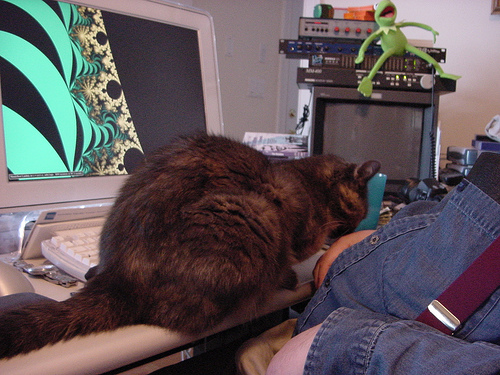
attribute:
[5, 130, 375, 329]
cat — black, sleeping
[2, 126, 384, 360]
cat — black, sleeping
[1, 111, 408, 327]
cat — calico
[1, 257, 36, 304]
computer mouse — gray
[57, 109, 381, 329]
cat — black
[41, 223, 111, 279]
keyboard — white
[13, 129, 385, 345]
cat — sleeping, black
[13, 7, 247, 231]
moniter — white, flat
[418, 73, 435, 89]
silver knob — large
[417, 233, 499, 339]
suspender — brown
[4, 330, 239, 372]
desk — white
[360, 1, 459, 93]
kermit — green, black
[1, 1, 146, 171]
image — white, black, green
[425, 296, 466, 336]
buckle — silver, metal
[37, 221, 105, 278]
keyboard — white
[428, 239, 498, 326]
strap — maroon, nylon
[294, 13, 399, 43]
electronics — gray, red, black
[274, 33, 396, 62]
electronics — black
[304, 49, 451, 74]
electronics — black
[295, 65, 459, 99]
electronics — black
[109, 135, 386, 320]
cat — black, sleeping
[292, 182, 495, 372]
shirt — denim, blue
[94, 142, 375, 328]
cat — calico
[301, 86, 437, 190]
television — small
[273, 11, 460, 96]
components — cable, video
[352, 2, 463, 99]
doll — Kermit the Frog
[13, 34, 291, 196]
monitor — computer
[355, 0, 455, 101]
frog — green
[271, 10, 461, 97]
electronics — black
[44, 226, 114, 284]
keyboard — white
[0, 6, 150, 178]
design — black, green, white, 3D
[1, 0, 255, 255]
monitor — computer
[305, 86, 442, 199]
tv — black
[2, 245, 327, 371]
desk — white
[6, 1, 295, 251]
screen — black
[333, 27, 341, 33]
knob — red, round, black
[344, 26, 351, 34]
knob — round, red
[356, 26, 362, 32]
knob — red, round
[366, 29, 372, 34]
knob — round, red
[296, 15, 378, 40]
machine — silver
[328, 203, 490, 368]
shirt — denim, blue